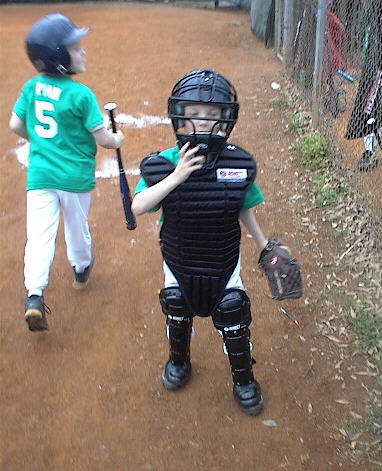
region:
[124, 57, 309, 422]
a boy wearing a catcher's outfit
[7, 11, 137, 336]
a boy going to bat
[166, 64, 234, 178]
a baseball catcher's helmet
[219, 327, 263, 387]
the shinguard on a catcher's uniform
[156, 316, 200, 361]
the shinguard on a catcher's uniform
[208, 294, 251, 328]
the knee-guard on a catcher's outfit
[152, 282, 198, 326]
the shinguard on a catcher's uniform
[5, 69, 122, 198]
a uniform with the number five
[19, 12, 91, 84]
a boy wearing a batter's helmet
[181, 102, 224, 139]
the face of a boy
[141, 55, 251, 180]
kid is wearing a helmet and mask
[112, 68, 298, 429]
boy is wearing protective gear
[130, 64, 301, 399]
Child in a catchers outfit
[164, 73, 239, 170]
Black helmet and face mask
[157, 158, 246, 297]
Catchers black body gear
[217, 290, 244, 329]
Black knee pad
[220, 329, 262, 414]
Black catchers boots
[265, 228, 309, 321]
Black and gray catchers mitt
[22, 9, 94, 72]
A black helmet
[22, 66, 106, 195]
A green tee shirt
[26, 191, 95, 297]
A white pair of pants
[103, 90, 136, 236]
A black bat with gold stripes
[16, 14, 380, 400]
kids playing baseball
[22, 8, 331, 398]
kids on a baseball field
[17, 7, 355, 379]
kids in a uniform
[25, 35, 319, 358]
kids in a baseball unifrom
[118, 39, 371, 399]
a kid wearing catching gear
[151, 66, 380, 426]
a kid with a mitt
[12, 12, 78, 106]
a kid with a helmet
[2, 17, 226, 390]
a kid holding a bat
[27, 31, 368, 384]
boys playing baseball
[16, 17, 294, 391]
boys on a baseball field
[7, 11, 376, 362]
boys are playing baseball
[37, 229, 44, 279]
a boy is wearing white pants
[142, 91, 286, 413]
a boy is a catcher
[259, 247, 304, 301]
the boy has a glove on the left hand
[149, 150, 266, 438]
the boy is protected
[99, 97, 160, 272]
the boy holds a bat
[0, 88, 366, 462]
picture taken outside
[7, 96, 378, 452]
picture taken during the day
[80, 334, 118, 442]
the ground is brown in color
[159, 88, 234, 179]
the boy is holding his mask